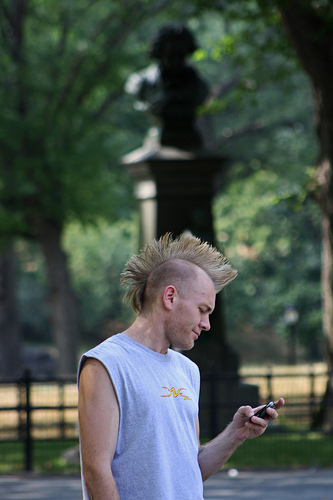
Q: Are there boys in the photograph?
A: No, there are no boys.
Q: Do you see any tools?
A: No, there are no tools.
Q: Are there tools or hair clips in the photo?
A: No, there are no tools or hair clips.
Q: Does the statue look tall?
A: Yes, the statue is tall.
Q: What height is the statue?
A: The statue is tall.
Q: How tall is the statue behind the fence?
A: The statue is tall.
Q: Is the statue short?
A: No, the statue is tall.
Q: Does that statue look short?
A: No, the statue is tall.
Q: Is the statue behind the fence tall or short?
A: The statue is tall.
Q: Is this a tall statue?
A: Yes, this is a tall statue.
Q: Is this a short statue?
A: No, this is a tall statue.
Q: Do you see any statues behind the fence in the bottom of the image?
A: Yes, there is a statue behind the fence.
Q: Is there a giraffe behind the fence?
A: No, there is a statue behind the fence.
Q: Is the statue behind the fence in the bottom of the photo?
A: Yes, the statue is behind the fence.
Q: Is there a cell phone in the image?
A: Yes, there is a cell phone.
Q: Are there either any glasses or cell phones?
A: Yes, there is a cell phone.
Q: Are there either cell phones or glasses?
A: Yes, there is a cell phone.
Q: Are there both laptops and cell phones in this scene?
A: No, there is a cell phone but no laptops.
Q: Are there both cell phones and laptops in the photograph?
A: No, there is a cell phone but no laptops.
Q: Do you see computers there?
A: No, there are no computers.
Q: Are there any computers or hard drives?
A: No, there are no computers or hard drives.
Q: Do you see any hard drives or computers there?
A: No, there are no computers or hard drives.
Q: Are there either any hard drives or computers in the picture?
A: No, there are no computers or hard drives.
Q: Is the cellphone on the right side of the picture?
A: Yes, the cellphone is on the right of the image.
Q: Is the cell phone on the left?
A: No, the cell phone is on the right of the image.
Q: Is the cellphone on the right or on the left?
A: The cellphone is on the right of the image.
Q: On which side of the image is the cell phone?
A: The cell phone is on the right of the image.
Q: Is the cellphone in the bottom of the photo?
A: Yes, the cellphone is in the bottom of the image.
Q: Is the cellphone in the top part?
A: No, the cellphone is in the bottom of the image.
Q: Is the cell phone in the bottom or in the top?
A: The cell phone is in the bottom of the image.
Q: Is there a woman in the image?
A: No, there are no women.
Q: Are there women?
A: No, there are no women.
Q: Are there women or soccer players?
A: No, there are no women or soccer players.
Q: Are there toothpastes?
A: No, there are no toothpastes.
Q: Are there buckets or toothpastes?
A: No, there are no toothpastes or buckets.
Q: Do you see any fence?
A: Yes, there is a fence.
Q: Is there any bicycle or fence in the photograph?
A: Yes, there is a fence.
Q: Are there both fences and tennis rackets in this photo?
A: No, there is a fence but no rackets.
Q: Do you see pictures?
A: No, there are no pictures.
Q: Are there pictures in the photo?
A: No, there are no pictures.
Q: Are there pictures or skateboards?
A: No, there are no pictures or skateboards.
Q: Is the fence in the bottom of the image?
A: Yes, the fence is in the bottom of the image.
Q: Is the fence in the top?
A: No, the fence is in the bottom of the image.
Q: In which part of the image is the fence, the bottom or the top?
A: The fence is in the bottom of the image.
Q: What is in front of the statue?
A: The fence is in front of the statue.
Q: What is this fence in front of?
A: The fence is in front of the statue.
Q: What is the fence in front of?
A: The fence is in front of the statue.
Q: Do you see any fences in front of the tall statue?
A: Yes, there is a fence in front of the statue.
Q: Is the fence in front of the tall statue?
A: Yes, the fence is in front of the statue.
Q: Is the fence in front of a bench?
A: No, the fence is in front of the statue.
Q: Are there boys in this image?
A: No, there are no boys.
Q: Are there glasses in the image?
A: No, there are no glasses.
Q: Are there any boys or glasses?
A: No, there are no glasses or boys.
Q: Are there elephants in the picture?
A: No, there are no elephants.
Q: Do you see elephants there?
A: No, there are no elephants.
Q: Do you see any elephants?
A: No, there are no elephants.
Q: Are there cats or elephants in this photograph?
A: No, there are no elephants or cats.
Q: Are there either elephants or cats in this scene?
A: No, there are no elephants or cats.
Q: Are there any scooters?
A: No, there are no scooters.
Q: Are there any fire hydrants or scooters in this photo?
A: No, there are no scooters or fire hydrants.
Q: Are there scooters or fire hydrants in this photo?
A: No, there are no scooters or fire hydrants.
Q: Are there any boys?
A: No, there are no boys.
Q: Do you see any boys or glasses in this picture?
A: No, there are no boys or glasses.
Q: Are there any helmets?
A: No, there are no helmets.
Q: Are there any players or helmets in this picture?
A: No, there are no helmets or players.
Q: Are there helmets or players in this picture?
A: No, there are no helmets or players.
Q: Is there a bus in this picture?
A: No, there are no buses.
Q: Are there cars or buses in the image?
A: No, there are no buses or cars.